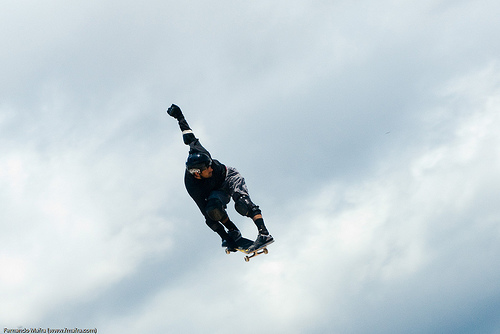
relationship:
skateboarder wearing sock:
[167, 99, 276, 260] [248, 215, 272, 236]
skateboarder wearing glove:
[167, 99, 276, 260] [167, 99, 184, 119]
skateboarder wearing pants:
[167, 99, 276, 260] [209, 167, 248, 205]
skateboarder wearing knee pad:
[167, 99, 276, 260] [234, 193, 254, 213]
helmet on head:
[190, 151, 212, 170] [189, 151, 214, 183]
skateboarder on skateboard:
[167, 99, 276, 260] [216, 231, 274, 259]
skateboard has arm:
[216, 231, 274, 259] [246, 250, 266, 257]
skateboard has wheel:
[216, 231, 274, 259] [245, 252, 252, 264]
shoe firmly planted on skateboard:
[247, 233, 275, 249] [216, 231, 274, 259]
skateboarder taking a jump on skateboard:
[167, 99, 276, 260] [216, 231, 274, 259]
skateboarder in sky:
[167, 99, 276, 260] [2, 6, 500, 332]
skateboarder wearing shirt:
[167, 99, 276, 260] [181, 144, 226, 215]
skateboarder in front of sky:
[167, 99, 276, 260] [2, 6, 500, 332]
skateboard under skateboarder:
[216, 231, 274, 259] [167, 99, 276, 260]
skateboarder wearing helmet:
[167, 99, 276, 260] [190, 151, 212, 170]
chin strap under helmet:
[197, 165, 206, 181] [190, 151, 212, 170]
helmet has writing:
[190, 151, 212, 170] [184, 165, 204, 179]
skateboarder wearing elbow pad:
[167, 99, 276, 260] [181, 130, 200, 144]